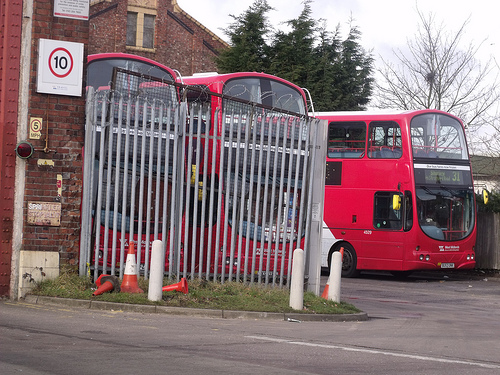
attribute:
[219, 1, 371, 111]
tree tops — green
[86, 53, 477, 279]
busses — three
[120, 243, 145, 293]
pylon — white, orange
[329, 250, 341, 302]
post — white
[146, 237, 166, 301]
post — white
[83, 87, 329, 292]
poles — metal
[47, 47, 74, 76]
circle — red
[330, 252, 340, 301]
post — white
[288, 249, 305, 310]
post — white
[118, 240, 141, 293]
cone — orange, white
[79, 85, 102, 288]
posts — grey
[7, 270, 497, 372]
lot — parking, grey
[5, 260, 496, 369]
lot — parking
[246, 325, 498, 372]
lines — white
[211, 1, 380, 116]
tree — green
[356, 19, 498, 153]
tree — bare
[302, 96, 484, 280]
bus — red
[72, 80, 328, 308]
gates — metal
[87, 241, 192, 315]
cones — three, orange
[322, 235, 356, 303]
cone — single, orange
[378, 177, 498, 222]
mirrors — yellow, side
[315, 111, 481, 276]
bus — red, white, double decker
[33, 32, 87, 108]
sign — white, red, black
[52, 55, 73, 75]
10 — circled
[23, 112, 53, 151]
sign — red, white, black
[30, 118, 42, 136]
5 — circled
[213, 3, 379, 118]
trees — cedar, group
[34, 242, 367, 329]
median — grassy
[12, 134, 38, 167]
light — red, reflection, caution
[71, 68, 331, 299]
fencing — metal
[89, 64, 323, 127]
wire — barbed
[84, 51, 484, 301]
buses — three, red, double decker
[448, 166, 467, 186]
31 — route number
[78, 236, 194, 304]
cones — three, orange, safety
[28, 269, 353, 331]
grass — small patch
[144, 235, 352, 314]
posts — four, white, circular, concrete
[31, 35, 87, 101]
sign — white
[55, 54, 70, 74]
10 — number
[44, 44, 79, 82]
circle — red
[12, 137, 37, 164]
light — red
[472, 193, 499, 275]
portion — small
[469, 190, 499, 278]
fence — wooden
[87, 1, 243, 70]
building — red brick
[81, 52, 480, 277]
buses — red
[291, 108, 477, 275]
bus — red, double decker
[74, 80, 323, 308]
fence — tall, metal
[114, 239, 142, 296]
cone — orange, white, traffic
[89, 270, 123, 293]
cone — traffic, orange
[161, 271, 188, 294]
cone — orange, traffic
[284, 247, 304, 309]
pole — white, concrete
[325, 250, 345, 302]
pole — concrete, white